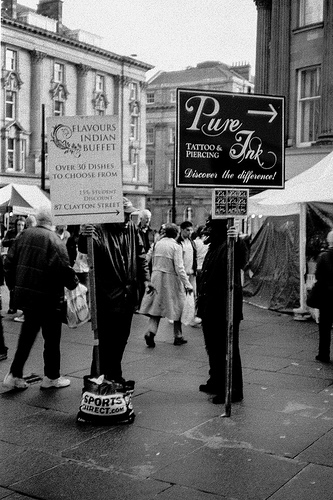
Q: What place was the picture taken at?
A: It was taken at the street.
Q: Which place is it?
A: It is a street.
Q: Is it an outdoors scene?
A: Yes, it is outdoors.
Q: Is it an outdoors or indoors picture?
A: It is outdoors.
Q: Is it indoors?
A: No, it is outdoors.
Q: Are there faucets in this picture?
A: No, there are no faucets.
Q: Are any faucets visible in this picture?
A: No, there are no faucets.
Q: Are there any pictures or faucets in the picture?
A: No, there are no faucets or pictures.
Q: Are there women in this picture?
A: Yes, there is a woman.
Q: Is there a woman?
A: Yes, there is a woman.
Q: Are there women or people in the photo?
A: Yes, there is a woman.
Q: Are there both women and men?
A: Yes, there are both a woman and a man.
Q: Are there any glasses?
A: No, there are no glasses.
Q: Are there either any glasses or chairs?
A: No, there are no glasses or chairs.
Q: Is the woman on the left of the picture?
A: Yes, the woman is on the left of the image.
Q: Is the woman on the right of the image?
A: No, the woman is on the left of the image.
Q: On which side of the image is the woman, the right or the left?
A: The woman is on the left of the image.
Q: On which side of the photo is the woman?
A: The woman is on the left of the image.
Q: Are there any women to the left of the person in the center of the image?
A: Yes, there is a woman to the left of the person.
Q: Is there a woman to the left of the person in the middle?
A: Yes, there is a woman to the left of the person.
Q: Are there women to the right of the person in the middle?
A: No, the woman is to the left of the person.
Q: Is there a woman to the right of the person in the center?
A: No, the woman is to the left of the person.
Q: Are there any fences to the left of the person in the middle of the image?
A: No, there is a woman to the left of the person.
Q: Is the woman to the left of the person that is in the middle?
A: Yes, the woman is to the left of the person.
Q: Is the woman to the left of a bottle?
A: No, the woman is to the left of the person.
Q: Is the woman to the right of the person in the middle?
A: No, the woman is to the left of the person.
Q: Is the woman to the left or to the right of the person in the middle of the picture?
A: The woman is to the left of the person.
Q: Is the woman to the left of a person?
A: Yes, the woman is to the left of a person.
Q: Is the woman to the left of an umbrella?
A: No, the woman is to the left of a person.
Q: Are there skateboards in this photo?
A: No, there are no skateboards.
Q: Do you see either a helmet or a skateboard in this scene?
A: No, there are no skateboards or helmets.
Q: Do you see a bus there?
A: No, there are no buses.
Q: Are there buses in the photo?
A: No, there are no buses.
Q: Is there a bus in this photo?
A: No, there are no buses.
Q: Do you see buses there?
A: No, there are no buses.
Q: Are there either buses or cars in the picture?
A: No, there are no buses or cars.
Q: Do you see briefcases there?
A: No, there are no briefcases.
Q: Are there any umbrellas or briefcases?
A: No, there are no briefcases or umbrellas.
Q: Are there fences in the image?
A: No, there are no fences.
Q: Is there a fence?
A: No, there are no fences.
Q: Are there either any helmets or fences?
A: No, there are no fences or helmets.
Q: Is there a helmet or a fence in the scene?
A: No, there are no fences or helmets.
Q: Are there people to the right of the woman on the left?
A: Yes, there is a person to the right of the woman.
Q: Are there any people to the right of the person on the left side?
A: Yes, there is a person to the right of the woman.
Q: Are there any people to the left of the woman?
A: No, the person is to the right of the woman.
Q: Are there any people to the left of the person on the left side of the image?
A: No, the person is to the right of the woman.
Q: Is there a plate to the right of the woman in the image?
A: No, there is a person to the right of the woman.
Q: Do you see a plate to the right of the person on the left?
A: No, there is a person to the right of the woman.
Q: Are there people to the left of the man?
A: Yes, there is a person to the left of the man.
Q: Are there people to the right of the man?
A: No, the person is to the left of the man.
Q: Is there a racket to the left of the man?
A: No, there is a person to the left of the man.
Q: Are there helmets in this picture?
A: No, there are no helmets.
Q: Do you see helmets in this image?
A: No, there are no helmets.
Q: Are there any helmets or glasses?
A: No, there are no helmets or glasses.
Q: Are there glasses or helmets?
A: No, there are no helmets or glasses.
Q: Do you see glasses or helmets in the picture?
A: No, there are no helmets or glasses.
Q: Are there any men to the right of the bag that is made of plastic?
A: Yes, there is a man to the right of the bag.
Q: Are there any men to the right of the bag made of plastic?
A: Yes, there is a man to the right of the bag.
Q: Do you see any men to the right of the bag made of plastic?
A: Yes, there is a man to the right of the bag.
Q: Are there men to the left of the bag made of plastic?
A: No, the man is to the right of the bag.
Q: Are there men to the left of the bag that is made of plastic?
A: No, the man is to the right of the bag.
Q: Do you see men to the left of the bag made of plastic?
A: No, the man is to the right of the bag.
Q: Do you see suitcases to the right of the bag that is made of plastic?
A: No, there is a man to the right of the bag.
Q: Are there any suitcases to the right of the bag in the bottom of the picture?
A: No, there is a man to the right of the bag.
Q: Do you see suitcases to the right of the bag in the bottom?
A: No, there is a man to the right of the bag.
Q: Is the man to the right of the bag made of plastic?
A: Yes, the man is to the right of the bag.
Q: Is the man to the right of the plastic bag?
A: Yes, the man is to the right of the bag.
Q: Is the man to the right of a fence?
A: No, the man is to the right of the bag.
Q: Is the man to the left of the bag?
A: No, the man is to the right of the bag.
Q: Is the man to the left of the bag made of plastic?
A: No, the man is to the right of the bag.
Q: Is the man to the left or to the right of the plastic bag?
A: The man is to the right of the bag.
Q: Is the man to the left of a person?
A: No, the man is to the right of a person.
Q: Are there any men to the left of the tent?
A: Yes, there is a man to the left of the tent.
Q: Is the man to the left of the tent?
A: Yes, the man is to the left of the tent.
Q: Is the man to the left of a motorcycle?
A: No, the man is to the left of the tent.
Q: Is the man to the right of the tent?
A: No, the man is to the left of the tent.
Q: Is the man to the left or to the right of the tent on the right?
A: The man is to the left of the tent.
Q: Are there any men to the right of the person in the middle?
A: Yes, there is a man to the right of the person.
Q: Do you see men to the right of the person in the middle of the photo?
A: Yes, there is a man to the right of the person.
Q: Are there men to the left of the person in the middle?
A: No, the man is to the right of the person.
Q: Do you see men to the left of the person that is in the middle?
A: No, the man is to the right of the person.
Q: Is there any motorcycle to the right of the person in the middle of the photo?
A: No, there is a man to the right of the person.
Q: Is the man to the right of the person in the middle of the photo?
A: Yes, the man is to the right of the person.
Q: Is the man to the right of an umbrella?
A: No, the man is to the right of the person.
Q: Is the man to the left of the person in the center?
A: No, the man is to the right of the person.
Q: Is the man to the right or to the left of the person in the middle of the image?
A: The man is to the right of the person.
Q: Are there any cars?
A: No, there are no cars.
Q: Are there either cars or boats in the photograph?
A: No, there are no cars or boats.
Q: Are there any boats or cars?
A: No, there are no cars or boats.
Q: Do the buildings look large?
A: Yes, the buildings are large.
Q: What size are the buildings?
A: The buildings are large.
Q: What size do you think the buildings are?
A: The buildings are large.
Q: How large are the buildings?
A: The buildings are large.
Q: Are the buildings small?
A: No, the buildings are large.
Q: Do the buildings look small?
A: No, the buildings are large.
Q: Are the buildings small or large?
A: The buildings are large.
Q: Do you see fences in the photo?
A: No, there are no fences.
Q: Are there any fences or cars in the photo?
A: No, there are no fences or cars.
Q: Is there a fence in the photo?
A: No, there are no fences.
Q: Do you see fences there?
A: No, there are no fences.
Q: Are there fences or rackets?
A: No, there are no fences or rackets.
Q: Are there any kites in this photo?
A: No, there are no kites.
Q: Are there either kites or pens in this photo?
A: No, there are no kites or pens.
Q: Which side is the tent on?
A: The tent is on the right of the image.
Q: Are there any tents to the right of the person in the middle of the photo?
A: Yes, there is a tent to the right of the person.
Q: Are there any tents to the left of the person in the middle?
A: No, the tent is to the right of the person.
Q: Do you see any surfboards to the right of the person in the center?
A: No, there is a tent to the right of the person.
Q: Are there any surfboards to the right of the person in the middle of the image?
A: No, there is a tent to the right of the person.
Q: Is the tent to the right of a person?
A: Yes, the tent is to the right of a person.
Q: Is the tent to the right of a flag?
A: No, the tent is to the right of a person.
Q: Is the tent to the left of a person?
A: No, the tent is to the right of a person.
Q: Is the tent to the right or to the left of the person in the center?
A: The tent is to the right of the person.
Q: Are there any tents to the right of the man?
A: Yes, there is a tent to the right of the man.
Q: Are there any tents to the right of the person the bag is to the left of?
A: Yes, there is a tent to the right of the man.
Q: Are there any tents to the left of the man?
A: No, the tent is to the right of the man.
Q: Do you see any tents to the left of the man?
A: No, the tent is to the right of the man.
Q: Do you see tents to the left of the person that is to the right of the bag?
A: No, the tent is to the right of the man.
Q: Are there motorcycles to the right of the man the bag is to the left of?
A: No, there is a tent to the right of the man.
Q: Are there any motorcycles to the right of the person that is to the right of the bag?
A: No, there is a tent to the right of the man.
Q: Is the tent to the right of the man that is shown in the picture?
A: Yes, the tent is to the right of the man.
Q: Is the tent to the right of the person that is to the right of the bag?
A: Yes, the tent is to the right of the man.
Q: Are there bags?
A: Yes, there is a bag.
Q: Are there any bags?
A: Yes, there is a bag.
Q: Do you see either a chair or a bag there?
A: Yes, there is a bag.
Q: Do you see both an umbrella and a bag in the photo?
A: No, there is a bag but no umbrellas.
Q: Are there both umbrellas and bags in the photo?
A: No, there is a bag but no umbrellas.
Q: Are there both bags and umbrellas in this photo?
A: No, there is a bag but no umbrellas.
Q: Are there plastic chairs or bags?
A: Yes, there is a plastic bag.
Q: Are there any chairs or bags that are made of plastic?
A: Yes, the bag is made of plastic.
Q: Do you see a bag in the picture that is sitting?
A: Yes, there is a bag that is sitting.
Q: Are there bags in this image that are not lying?
A: Yes, there is a bag that is sitting.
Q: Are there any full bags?
A: Yes, there is a full bag.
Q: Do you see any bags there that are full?
A: Yes, there is a bag that is full.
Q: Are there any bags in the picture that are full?
A: Yes, there is a bag that is full.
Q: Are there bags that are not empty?
A: Yes, there is an full bag.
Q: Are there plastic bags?
A: Yes, there is a bag that is made of plastic.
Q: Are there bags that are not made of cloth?
A: Yes, there is a bag that is made of plastic.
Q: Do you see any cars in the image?
A: No, there are no cars.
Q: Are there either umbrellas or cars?
A: No, there are no cars or umbrellas.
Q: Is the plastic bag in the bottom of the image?
A: Yes, the bag is in the bottom of the image.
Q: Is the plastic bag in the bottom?
A: Yes, the bag is in the bottom of the image.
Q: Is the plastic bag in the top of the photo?
A: No, the bag is in the bottom of the image.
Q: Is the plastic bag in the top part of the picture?
A: No, the bag is in the bottom of the image.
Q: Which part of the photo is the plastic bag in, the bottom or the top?
A: The bag is in the bottom of the image.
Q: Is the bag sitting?
A: Yes, the bag is sitting.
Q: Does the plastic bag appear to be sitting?
A: Yes, the bag is sitting.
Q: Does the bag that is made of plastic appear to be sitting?
A: Yes, the bag is sitting.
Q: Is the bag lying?
A: No, the bag is sitting.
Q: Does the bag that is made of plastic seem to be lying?
A: No, the bag is sitting.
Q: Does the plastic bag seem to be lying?
A: No, the bag is sitting.